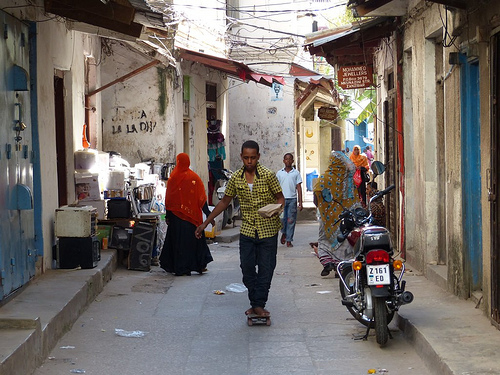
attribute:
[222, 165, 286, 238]
shirt — yellow, black, blue, checkered, white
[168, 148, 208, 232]
scarf — red, orange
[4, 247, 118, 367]
sidewalk — small, narrow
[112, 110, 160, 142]
graffiti — balck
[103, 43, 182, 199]
wall — white, dirty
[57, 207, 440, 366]
street — busy, tight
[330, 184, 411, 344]
bike — parked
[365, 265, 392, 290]
plate — license, black, white, square, silver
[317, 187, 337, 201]
mirror — rear view, circle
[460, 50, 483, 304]
door — blue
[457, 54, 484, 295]
trim — painted, light blue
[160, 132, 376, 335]
people — walking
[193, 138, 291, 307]
kid — riding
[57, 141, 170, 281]
pile — material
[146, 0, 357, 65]
wires — electric, suspended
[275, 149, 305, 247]
man — young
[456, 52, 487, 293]
doorway — blue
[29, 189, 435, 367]
alley — paved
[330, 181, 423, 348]
motorbike — parked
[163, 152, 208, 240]
fabric — red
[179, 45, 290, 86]
awning — red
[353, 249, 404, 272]
lights — red, yellow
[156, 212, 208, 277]
dress — long, black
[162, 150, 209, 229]
jihab — red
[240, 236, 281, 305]
pants — black, used, dark, boy's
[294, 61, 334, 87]
roof — red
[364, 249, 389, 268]
stoplight — red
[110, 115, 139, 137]
la la — written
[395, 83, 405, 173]
pole — red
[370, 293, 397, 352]
tire — back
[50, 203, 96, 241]
box — beige